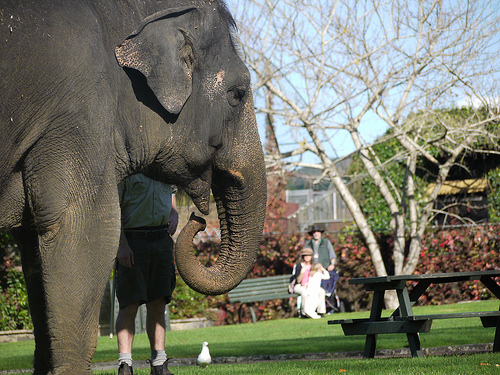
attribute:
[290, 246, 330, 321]
person — white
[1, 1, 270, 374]
elephant — large, grey, gray, docile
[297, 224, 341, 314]
person — white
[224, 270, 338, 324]
bench — green, wood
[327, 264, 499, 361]
picnic table — green, dark green, wood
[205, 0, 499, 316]
tree — bare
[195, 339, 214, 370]
bird — white, little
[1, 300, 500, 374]
ground — green, well manicured, bright green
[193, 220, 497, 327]
leaves — red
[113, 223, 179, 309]
shorts — green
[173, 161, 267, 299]
trunk — long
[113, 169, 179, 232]
shirt — grey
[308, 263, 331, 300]
child — white, young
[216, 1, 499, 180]
sky — blue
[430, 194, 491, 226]
window — clear